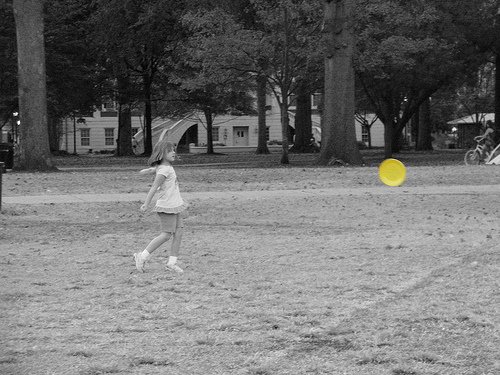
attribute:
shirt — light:
[153, 164, 190, 214]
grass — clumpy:
[224, 281, 339, 321]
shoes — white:
[95, 240, 179, 264]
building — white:
[13, 51, 195, 176]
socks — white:
[138, 250, 178, 267]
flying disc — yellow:
[363, 149, 413, 201]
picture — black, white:
[5, 1, 497, 372]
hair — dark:
[144, 137, 178, 165]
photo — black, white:
[4, 6, 496, 373]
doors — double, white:
[217, 114, 255, 148]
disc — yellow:
[372, 152, 412, 187]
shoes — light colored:
[124, 242, 150, 275]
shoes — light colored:
[162, 253, 191, 278]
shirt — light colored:
[150, 163, 190, 208]